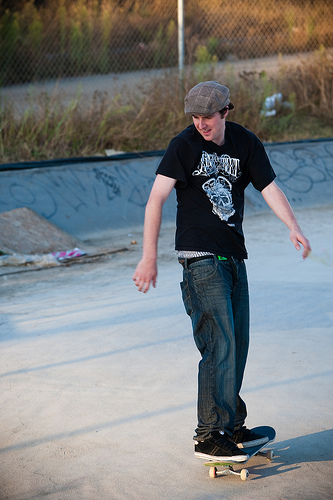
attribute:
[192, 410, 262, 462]
shoes — black, white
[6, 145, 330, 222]
graffiti — written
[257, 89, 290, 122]
trash — thrown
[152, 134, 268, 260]
t shirt — black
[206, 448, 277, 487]
wheels — white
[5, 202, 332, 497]
ground — surface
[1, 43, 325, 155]
grass — brown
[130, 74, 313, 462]
man — smiling, young, skateboarding, riding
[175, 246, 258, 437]
jeans — blue